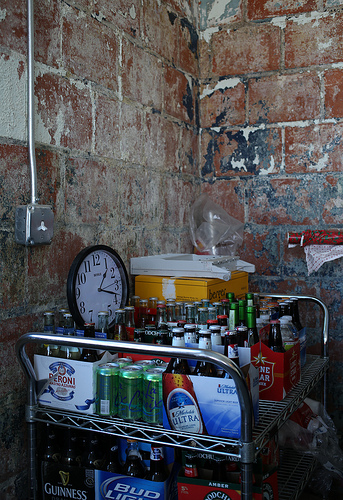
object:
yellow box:
[134, 268, 250, 301]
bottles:
[244, 291, 258, 328]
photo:
[0, 0, 340, 496]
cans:
[96, 357, 120, 419]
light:
[33, 209, 54, 241]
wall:
[33, 2, 338, 198]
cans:
[117, 369, 144, 418]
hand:
[94, 264, 112, 287]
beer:
[116, 363, 142, 420]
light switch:
[21, 204, 59, 247]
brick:
[92, 92, 183, 169]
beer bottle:
[162, 372, 207, 433]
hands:
[97, 286, 123, 299]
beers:
[80, 322, 96, 362]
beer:
[143, 370, 162, 423]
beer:
[95, 364, 120, 418]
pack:
[93, 437, 174, 500]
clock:
[68, 242, 129, 336]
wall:
[0, 2, 343, 500]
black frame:
[66, 243, 131, 331]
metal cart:
[16, 289, 331, 500]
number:
[89, 253, 102, 266]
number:
[75, 299, 87, 318]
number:
[73, 269, 86, 287]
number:
[100, 255, 109, 269]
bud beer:
[95, 437, 174, 498]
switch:
[38, 218, 47, 234]